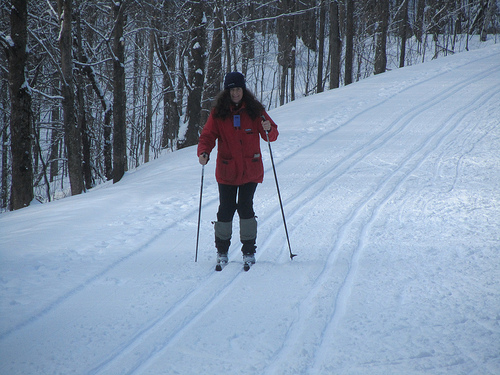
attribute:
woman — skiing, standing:
[197, 68, 278, 273]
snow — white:
[6, 42, 496, 375]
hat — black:
[224, 70, 249, 89]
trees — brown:
[1, 2, 499, 212]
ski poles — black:
[192, 113, 298, 263]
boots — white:
[212, 238, 260, 272]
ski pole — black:
[263, 129, 298, 261]